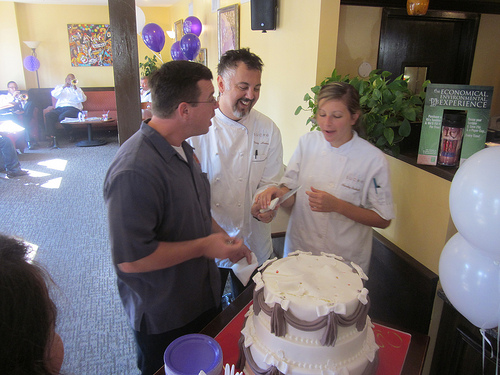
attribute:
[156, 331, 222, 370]
plates — purple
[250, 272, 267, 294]
bow — white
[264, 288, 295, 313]
bow — white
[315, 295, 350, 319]
bow — white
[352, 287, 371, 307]
bow — white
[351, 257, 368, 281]
bow — white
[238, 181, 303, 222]
knife — white, silver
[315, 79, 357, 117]
hair — brown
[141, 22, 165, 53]
balloon — Purple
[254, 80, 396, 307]
woman — white-clothed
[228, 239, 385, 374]
wedding cake — white, brown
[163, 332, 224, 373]
plates — Purple 